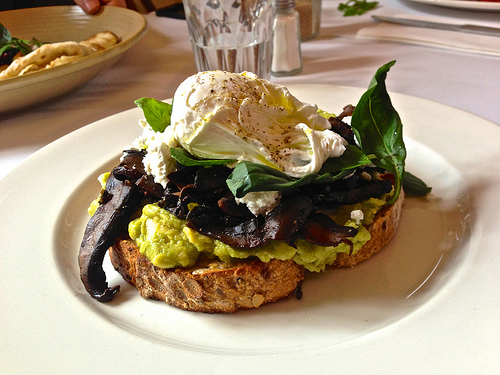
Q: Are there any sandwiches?
A: Yes, there is a sandwich.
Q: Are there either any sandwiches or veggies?
A: Yes, there is a sandwich.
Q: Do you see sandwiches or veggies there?
A: Yes, there is a sandwich.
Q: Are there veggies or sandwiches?
A: Yes, there is a sandwich.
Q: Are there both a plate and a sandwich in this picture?
A: Yes, there are both a sandwich and a plate.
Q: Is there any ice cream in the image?
A: No, there is no ice cream.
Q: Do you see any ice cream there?
A: No, there is no ice cream.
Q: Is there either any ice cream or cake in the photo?
A: No, there are no ice cream or cakes.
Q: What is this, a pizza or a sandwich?
A: This is a sandwich.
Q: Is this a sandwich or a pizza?
A: This is a sandwich.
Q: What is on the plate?
A: The sandwich is on the plate.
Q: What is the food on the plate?
A: The food is a sandwich.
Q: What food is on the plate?
A: The food is a sandwich.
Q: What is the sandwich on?
A: The sandwich is on the plate.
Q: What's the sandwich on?
A: The sandwich is on the plate.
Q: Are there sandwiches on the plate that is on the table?
A: Yes, there is a sandwich on the plate.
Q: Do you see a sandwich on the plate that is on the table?
A: Yes, there is a sandwich on the plate.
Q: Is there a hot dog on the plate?
A: No, there is a sandwich on the plate.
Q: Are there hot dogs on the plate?
A: No, there is a sandwich on the plate.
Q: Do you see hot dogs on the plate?
A: No, there is a sandwich on the plate.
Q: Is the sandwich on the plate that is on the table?
A: Yes, the sandwich is on the plate.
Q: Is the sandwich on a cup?
A: No, the sandwich is on the plate.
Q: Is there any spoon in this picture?
A: No, there are no spoons.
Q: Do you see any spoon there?
A: No, there are no spoons.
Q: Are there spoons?
A: No, there are no spoons.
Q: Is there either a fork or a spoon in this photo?
A: No, there are no spoons or forks.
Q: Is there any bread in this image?
A: Yes, there is a bread.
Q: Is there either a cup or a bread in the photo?
A: Yes, there is a bread.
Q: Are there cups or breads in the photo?
A: Yes, there is a bread.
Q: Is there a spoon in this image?
A: No, there are no spoons.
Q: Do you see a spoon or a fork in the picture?
A: No, there are no spoons or forks.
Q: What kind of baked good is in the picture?
A: The baked good is a bread.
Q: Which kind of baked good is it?
A: The food is a bread.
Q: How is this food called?
A: This is a bread.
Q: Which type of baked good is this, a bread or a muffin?
A: This is a bread.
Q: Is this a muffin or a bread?
A: This is a bread.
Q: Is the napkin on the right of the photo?
A: Yes, the napkin is on the right of the image.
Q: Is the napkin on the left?
A: No, the napkin is on the right of the image.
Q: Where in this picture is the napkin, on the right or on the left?
A: The napkin is on the right of the image.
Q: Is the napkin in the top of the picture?
A: Yes, the napkin is in the top of the image.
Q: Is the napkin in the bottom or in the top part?
A: The napkin is in the top of the image.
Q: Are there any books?
A: No, there are no books.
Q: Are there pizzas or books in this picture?
A: No, there are no books or pizzas.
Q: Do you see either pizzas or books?
A: No, there are no books or pizzas.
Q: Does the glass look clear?
A: Yes, the glass is clear.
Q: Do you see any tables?
A: Yes, there is a table.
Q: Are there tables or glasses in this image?
A: Yes, there is a table.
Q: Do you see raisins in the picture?
A: No, there are no raisins.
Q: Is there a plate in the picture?
A: Yes, there is a plate.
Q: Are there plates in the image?
A: Yes, there is a plate.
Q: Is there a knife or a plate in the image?
A: Yes, there is a plate.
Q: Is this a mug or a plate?
A: This is a plate.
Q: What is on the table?
A: The plate is on the table.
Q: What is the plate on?
A: The plate is on the table.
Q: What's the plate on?
A: The plate is on the table.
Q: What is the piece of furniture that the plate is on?
A: The piece of furniture is a table.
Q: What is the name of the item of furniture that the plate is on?
A: The piece of furniture is a table.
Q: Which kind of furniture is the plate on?
A: The plate is on the table.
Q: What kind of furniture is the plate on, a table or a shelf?
A: The plate is on a table.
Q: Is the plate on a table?
A: Yes, the plate is on a table.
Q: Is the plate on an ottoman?
A: No, the plate is on a table.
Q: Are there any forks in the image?
A: No, there are no forks.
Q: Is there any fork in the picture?
A: No, there are no forks.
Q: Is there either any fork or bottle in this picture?
A: No, there are no forks or bottles.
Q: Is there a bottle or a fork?
A: No, there are no forks or bottles.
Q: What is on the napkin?
A: The silverware is on the napkin.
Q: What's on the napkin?
A: The silverware is on the napkin.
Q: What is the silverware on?
A: The silverware is on the napkin.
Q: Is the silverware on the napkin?
A: Yes, the silverware is on the napkin.